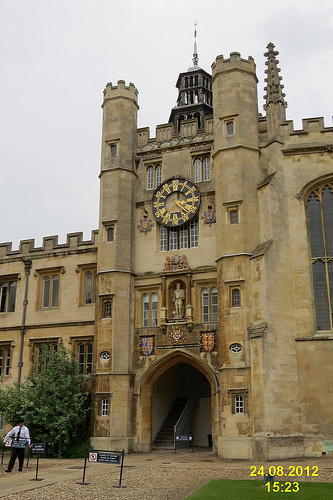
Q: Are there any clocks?
A: Yes, there is a clock.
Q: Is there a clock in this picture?
A: Yes, there is a clock.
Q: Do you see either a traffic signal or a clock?
A: Yes, there is a clock.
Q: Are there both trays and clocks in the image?
A: No, there is a clock but no trays.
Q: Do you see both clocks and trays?
A: No, there is a clock but no trays.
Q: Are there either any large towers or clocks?
A: Yes, there is a large clock.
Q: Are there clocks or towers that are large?
A: Yes, the clock is large.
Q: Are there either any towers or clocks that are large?
A: Yes, the clock is large.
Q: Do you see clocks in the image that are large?
A: Yes, there is a large clock.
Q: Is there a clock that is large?
A: Yes, there is a clock that is large.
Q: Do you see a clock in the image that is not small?
A: Yes, there is a large clock.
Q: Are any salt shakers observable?
A: No, there are no salt shakers.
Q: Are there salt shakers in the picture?
A: No, there are no salt shakers.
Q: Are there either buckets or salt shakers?
A: No, there are no salt shakers or buckets.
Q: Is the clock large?
A: Yes, the clock is large.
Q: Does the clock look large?
A: Yes, the clock is large.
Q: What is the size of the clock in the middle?
A: The clock is large.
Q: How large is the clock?
A: The clock is large.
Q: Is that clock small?
A: No, the clock is large.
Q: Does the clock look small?
A: No, the clock is large.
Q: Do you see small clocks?
A: No, there is a clock but it is large.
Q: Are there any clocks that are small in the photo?
A: No, there is a clock but it is large.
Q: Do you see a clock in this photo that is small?
A: No, there is a clock but it is large.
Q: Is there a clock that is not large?
A: No, there is a clock but it is large.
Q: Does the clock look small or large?
A: The clock is large.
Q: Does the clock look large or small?
A: The clock is large.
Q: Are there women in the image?
A: No, there are no women.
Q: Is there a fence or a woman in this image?
A: No, there are no women or fences.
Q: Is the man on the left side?
A: Yes, the man is on the left of the image.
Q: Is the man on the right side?
A: No, the man is on the left of the image.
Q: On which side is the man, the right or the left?
A: The man is on the left of the image.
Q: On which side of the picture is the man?
A: The man is on the left of the image.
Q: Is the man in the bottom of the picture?
A: Yes, the man is in the bottom of the image.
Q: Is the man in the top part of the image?
A: No, the man is in the bottom of the image.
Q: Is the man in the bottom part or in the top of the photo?
A: The man is in the bottom of the image.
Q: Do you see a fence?
A: No, there are no fences.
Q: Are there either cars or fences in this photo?
A: No, there are no fences or cars.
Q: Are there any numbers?
A: Yes, there are numbers.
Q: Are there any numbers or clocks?
A: Yes, there are numbers.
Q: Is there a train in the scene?
A: No, there are no trains.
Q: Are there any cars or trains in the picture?
A: No, there are no trains or cars.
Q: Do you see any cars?
A: No, there are no cars.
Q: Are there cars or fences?
A: No, there are no cars or fences.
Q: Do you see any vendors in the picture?
A: No, there are no vendors.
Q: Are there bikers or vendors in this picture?
A: No, there are no vendors or bikers.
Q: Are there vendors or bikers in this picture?
A: No, there are no vendors or bikers.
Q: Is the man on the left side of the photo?
A: Yes, the man is on the left of the image.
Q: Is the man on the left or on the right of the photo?
A: The man is on the left of the image.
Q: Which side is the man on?
A: The man is on the left of the image.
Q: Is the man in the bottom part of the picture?
A: Yes, the man is in the bottom of the image.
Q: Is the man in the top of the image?
A: No, the man is in the bottom of the image.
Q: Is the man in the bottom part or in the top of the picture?
A: The man is in the bottom of the image.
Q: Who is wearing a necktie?
A: The man is wearing a necktie.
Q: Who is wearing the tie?
A: The man is wearing a necktie.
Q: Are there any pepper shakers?
A: No, there are no pepper shakers.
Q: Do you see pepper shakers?
A: No, there are no pepper shakers.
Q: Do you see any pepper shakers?
A: No, there are no pepper shakers.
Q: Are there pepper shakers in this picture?
A: No, there are no pepper shakers.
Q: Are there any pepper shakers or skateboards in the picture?
A: No, there are no pepper shakers or skateboards.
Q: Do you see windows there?
A: Yes, there is a window.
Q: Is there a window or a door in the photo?
A: Yes, there is a window.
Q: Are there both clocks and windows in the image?
A: Yes, there are both a window and a clock.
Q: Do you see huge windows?
A: Yes, there is a huge window.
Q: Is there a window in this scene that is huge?
A: Yes, there is a window that is huge.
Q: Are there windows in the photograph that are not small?
A: Yes, there is a huge window.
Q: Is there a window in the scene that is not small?
A: Yes, there is a huge window.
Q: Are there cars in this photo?
A: No, there are no cars.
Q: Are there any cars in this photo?
A: No, there are no cars.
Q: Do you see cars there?
A: No, there are no cars.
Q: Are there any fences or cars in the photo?
A: No, there are no cars or fences.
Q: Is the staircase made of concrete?
A: Yes, the staircase is made of concrete.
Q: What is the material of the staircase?
A: The staircase is made of cement.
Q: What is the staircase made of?
A: The staircase is made of concrete.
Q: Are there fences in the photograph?
A: No, there are no fences.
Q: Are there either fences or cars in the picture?
A: No, there are no fences or cars.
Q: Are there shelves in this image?
A: No, there are no shelves.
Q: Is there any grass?
A: Yes, there is grass.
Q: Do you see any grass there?
A: Yes, there is grass.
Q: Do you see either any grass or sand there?
A: Yes, there is grass.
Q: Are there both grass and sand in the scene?
A: No, there is grass but no sand.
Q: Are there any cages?
A: No, there are no cages.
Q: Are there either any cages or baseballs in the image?
A: No, there are no cages or baseballs.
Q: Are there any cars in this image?
A: No, there are no cars.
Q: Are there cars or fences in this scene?
A: No, there are no cars or fences.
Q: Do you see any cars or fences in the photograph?
A: No, there are no cars or fences.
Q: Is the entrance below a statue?
A: Yes, the entrance is below a statue.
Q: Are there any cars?
A: No, there are no cars.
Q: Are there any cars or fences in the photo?
A: No, there are no cars or fences.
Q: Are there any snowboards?
A: No, there are no snowboards.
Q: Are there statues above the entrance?
A: Yes, there is a statue above the entrance.